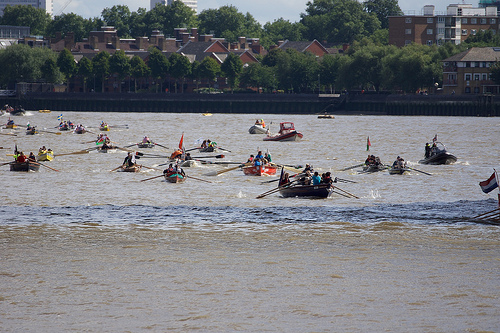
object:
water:
[7, 111, 498, 333]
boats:
[277, 165, 334, 199]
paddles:
[331, 185, 358, 199]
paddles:
[256, 179, 299, 198]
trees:
[193, 51, 220, 92]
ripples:
[8, 200, 499, 235]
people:
[311, 172, 322, 186]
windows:
[405, 28, 413, 35]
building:
[444, 46, 500, 95]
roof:
[389, 11, 499, 21]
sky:
[46, 1, 479, 30]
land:
[2, 93, 499, 115]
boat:
[11, 161, 41, 171]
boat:
[277, 183, 332, 199]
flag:
[479, 167, 499, 194]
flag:
[176, 131, 185, 152]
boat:
[169, 150, 189, 163]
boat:
[37, 150, 53, 160]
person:
[17, 152, 27, 163]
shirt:
[17, 155, 27, 162]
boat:
[264, 122, 303, 142]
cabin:
[279, 121, 296, 132]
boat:
[243, 164, 277, 175]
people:
[246, 154, 254, 163]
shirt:
[312, 176, 321, 183]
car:
[200, 89, 223, 94]